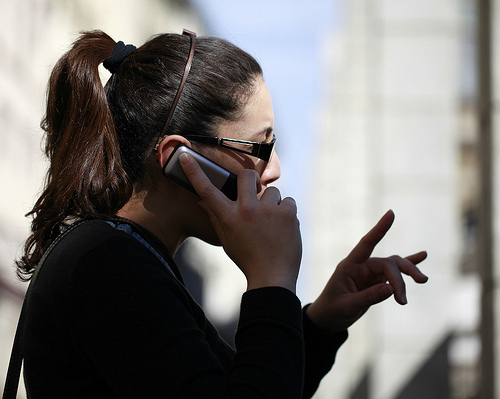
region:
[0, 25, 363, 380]
this is a lady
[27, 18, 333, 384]
the lady is speaking through the phone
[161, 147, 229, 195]
this is a cell phone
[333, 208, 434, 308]
these are the fingers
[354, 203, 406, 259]
the finger is pointing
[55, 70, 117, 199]
this is the hair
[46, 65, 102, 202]
the hair is long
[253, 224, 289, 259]
the lady is light skinned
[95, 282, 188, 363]
the blouse is black in color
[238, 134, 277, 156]
she is wearing spectacles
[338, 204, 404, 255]
woman's finger pointing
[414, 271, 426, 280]
nail on woman's finger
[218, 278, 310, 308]
sleeve on black shirt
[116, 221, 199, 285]
blue bag strap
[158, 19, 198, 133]
brown hair band over hair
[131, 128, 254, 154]
glass frame over ear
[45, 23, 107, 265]
long brown pony tail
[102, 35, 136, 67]
blue hair holder on hair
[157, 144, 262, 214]
silver and black cell phone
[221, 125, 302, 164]
woman wearing eye glass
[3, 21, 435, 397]
woman talking on a cellphone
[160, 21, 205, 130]
brown headband of woman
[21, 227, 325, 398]
black long sleeve shirt of woman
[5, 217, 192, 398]
strap of woman's bag on her shoulder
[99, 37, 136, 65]
ponytail holder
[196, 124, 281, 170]
sun glasses woman is wearing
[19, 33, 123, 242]
ponytail of the woman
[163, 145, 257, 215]
cellphone woman is talking on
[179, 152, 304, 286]
hand holding the cellphone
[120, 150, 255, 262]
shadow on woman's face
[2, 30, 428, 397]
Woman near the camera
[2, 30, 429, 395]
Woman talking on phone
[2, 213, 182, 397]
Strap on woman's shoulder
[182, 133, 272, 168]
Woman is wearing glasses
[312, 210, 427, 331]
Woman making hand gesture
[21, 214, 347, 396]
The sweater is blue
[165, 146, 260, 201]
Phone is silver and black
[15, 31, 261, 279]
Woman's hair is brown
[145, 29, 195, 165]
Head band is brown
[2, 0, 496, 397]
Buildings in the background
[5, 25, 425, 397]
side of woman on phone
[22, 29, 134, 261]
brown hair in pony tail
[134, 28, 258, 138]
brown band in hair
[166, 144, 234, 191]
cell phone against ear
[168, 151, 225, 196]
index finger on cell phone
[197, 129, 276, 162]
side of glasses on face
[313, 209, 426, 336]
hand with pointing finger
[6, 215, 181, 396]
purse strap on shoulder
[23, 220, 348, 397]
sweater with long sleeves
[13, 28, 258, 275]
brunette hair pulled back